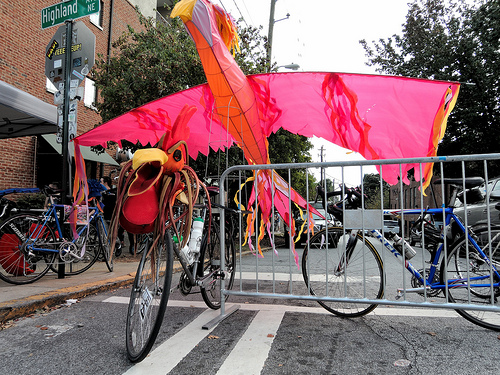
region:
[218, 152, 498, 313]
A bicycle rack on the street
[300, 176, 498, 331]
A bicycle by the bicycle rack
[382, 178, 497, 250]
Cars parked on the street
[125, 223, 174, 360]
The front tire of the bicycle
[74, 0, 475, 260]
A kite near the bicycles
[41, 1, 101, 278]
A street sign on the sidewalk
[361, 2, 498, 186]
A tree by the parked cars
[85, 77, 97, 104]
A window on the building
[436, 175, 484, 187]
The seat of the bicycle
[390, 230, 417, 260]
A water bottle on the bicycle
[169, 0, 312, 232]
a long bird type kite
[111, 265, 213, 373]
tire of the cycle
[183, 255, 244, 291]
pedal of the cycle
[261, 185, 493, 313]
a cycle parked in road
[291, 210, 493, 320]
a cycle next to gate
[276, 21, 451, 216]
a wing of the kite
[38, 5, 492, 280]
a beautiful big kite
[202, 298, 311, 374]
white lines in the road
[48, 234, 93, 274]
small pedal of the cycle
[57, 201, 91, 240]
the bike is blue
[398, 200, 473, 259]
the bike is leaning on the gate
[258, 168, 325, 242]
the gate is gray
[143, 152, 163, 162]
the beak is yellow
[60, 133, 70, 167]
the pole is black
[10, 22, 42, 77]
the building is brown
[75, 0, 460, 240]
An orange and pink balloon in the shape of a bird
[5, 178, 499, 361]
Some parked cycles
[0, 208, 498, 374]
grey cemented road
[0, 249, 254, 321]
sidewalk by the roadside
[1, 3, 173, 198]
A brown brick building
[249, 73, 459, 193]
One of the wings of the toy bird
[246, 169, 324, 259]
Beautiful tail plume of the balloon bird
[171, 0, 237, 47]
The head and crest on it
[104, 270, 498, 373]
White marking lines on the road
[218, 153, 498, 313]
Barricade of blue metal rods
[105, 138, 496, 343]
bikes on the bike rack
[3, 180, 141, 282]
bikes on the sidewalk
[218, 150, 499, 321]
rack for holding bikes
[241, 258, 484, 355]
street for vehicles to travel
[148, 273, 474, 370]
white strip on ground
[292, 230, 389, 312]
front tire of bike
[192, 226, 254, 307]
rear tire of bike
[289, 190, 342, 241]
vehicles on the street